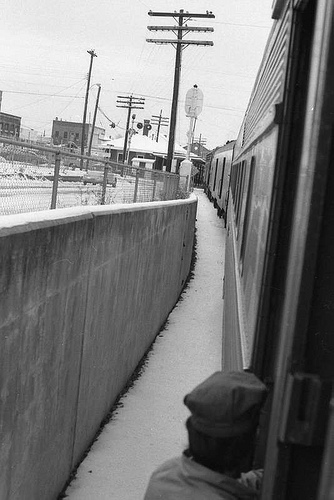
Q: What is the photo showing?
A: It is showing a train station.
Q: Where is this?
A: This is at the train station.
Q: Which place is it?
A: It is a train station.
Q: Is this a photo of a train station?
A: Yes, it is showing a train station.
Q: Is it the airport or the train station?
A: It is the train station.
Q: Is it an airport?
A: No, it is a train station.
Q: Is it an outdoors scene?
A: Yes, it is outdoors.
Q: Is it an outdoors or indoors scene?
A: It is outdoors.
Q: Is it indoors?
A: No, it is outdoors.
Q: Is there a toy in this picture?
A: No, there are no toys.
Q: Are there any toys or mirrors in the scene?
A: No, there are no toys or mirrors.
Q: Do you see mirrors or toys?
A: No, there are no toys or mirrors.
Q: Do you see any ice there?
A: Yes, there is ice.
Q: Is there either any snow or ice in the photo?
A: Yes, there is ice.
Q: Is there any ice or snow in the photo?
A: Yes, there is ice.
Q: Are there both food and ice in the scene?
A: No, there is ice but no food.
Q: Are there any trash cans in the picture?
A: No, there are no trash cans.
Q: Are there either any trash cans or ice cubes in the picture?
A: No, there are no trash cans or ice cubes.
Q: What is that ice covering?
A: The ice is covering the ground.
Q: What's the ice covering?
A: The ice is covering the ground.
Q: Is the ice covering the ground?
A: Yes, the ice is covering the ground.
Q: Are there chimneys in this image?
A: No, there are no chimneys.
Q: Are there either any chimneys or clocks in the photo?
A: No, there are no chimneys or clocks.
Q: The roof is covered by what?
A: The roof is covered by the snow.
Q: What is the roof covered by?
A: The roof is covered by the snow.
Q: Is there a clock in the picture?
A: No, there are no clocks.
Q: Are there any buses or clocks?
A: No, there are no clocks or buses.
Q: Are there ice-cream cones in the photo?
A: No, there are no ice-cream cones.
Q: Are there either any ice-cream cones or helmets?
A: No, there are no ice-cream cones or helmets.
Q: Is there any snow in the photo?
A: Yes, there is snow.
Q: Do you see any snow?
A: Yes, there is snow.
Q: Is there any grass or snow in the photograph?
A: Yes, there is snow.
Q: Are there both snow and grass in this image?
A: No, there is snow but no grass.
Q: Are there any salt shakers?
A: No, there are no salt shakers.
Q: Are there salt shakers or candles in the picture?
A: No, there are no salt shakers or candles.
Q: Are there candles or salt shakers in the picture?
A: No, there are no salt shakers or candles.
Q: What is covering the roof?
A: The snow is covering the roof.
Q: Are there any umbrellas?
A: No, there are no umbrellas.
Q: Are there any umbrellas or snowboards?
A: No, there are no umbrellas or snowboards.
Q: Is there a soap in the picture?
A: No, there are no soaps.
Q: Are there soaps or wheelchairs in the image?
A: No, there are no soaps or wheelchairs.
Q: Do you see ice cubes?
A: No, there are no ice cubes.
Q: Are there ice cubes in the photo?
A: No, there are no ice cubes.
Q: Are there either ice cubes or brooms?
A: No, there are no ice cubes or brooms.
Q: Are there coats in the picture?
A: Yes, there is a coat.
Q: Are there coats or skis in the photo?
A: Yes, there is a coat.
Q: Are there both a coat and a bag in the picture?
A: No, there is a coat but no bags.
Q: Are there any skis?
A: No, there are no skis.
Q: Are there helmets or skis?
A: No, there are no skis or helmets.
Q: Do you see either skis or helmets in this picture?
A: No, there are no skis or helmets.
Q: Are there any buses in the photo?
A: No, there are no buses.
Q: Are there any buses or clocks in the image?
A: No, there are no buses or clocks.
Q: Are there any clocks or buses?
A: No, there are no buses or clocks.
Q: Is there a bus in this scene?
A: No, there are no buses.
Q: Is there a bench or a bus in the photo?
A: No, there are no buses or benches.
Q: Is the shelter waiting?
A: Yes, the shelter is waiting.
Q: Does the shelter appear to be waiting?
A: Yes, the shelter is waiting.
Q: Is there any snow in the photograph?
A: Yes, there is snow.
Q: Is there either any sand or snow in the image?
A: Yes, there is snow.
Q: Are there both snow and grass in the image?
A: No, there is snow but no grass.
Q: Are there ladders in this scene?
A: No, there are no ladders.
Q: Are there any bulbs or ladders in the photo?
A: No, there are no ladders or bulbs.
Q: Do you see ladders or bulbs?
A: No, there are no ladders or bulbs.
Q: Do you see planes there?
A: No, there are no planes.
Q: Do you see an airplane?
A: No, there are no airplanes.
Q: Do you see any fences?
A: Yes, there is a fence.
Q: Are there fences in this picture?
A: Yes, there is a fence.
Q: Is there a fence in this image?
A: Yes, there is a fence.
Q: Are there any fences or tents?
A: Yes, there is a fence.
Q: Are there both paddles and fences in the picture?
A: No, there is a fence but no paddles.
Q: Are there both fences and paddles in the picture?
A: No, there is a fence but no paddles.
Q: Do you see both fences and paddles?
A: No, there is a fence but no paddles.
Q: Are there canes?
A: No, there are no canes.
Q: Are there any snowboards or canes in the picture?
A: No, there are no canes or snowboards.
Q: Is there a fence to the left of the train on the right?
A: Yes, there is a fence to the left of the train.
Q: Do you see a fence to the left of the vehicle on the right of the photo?
A: Yes, there is a fence to the left of the train.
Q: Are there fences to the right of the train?
A: No, the fence is to the left of the train.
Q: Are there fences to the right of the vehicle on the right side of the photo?
A: No, the fence is to the left of the train.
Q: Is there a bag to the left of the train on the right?
A: No, there is a fence to the left of the train.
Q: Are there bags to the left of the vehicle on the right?
A: No, there is a fence to the left of the train.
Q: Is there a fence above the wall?
A: Yes, there is a fence above the wall.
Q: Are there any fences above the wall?
A: Yes, there is a fence above the wall.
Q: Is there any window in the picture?
A: Yes, there is a window.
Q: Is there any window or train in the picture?
A: Yes, there is a window.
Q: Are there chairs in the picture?
A: No, there are no chairs.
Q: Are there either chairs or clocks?
A: No, there are no chairs or clocks.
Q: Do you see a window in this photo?
A: Yes, there is a window.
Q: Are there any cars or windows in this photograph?
A: Yes, there is a window.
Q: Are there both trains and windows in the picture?
A: Yes, there are both a window and a train.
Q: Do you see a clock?
A: No, there are no clocks.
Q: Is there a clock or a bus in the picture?
A: No, there are no clocks or buses.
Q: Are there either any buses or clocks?
A: No, there are no clocks or buses.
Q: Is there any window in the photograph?
A: Yes, there is a window.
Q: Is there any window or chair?
A: Yes, there is a window.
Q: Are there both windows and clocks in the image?
A: No, there is a window but no clocks.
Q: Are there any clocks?
A: No, there are no clocks.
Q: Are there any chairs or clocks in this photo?
A: No, there are no clocks or chairs.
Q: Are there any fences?
A: Yes, there is a fence.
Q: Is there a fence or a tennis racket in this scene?
A: Yes, there is a fence.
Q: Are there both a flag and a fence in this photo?
A: No, there is a fence but no flags.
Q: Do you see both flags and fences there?
A: No, there is a fence but no flags.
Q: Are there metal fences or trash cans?
A: Yes, there is a metal fence.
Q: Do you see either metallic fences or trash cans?
A: Yes, there is a metal fence.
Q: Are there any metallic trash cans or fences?
A: Yes, there is a metal fence.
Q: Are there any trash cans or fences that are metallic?
A: Yes, the fence is metallic.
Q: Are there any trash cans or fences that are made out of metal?
A: Yes, the fence is made of metal.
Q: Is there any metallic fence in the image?
A: Yes, there is a metal fence.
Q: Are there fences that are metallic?
A: Yes, there is a fence that is metallic.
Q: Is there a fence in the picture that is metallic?
A: Yes, there is a fence that is metallic.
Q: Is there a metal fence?
A: Yes, there is a fence that is made of metal.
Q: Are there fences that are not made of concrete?
A: Yes, there is a fence that is made of metal.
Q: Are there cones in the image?
A: No, there are no cones.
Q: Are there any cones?
A: No, there are no cones.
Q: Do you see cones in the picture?
A: No, there are no cones.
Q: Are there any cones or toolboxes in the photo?
A: No, there are no cones or toolboxes.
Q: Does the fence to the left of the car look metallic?
A: Yes, the fence is metallic.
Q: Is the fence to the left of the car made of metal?
A: Yes, the fence is made of metal.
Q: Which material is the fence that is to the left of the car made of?
A: The fence is made of metal.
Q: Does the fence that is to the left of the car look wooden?
A: No, the fence is metallic.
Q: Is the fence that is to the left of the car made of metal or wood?
A: The fence is made of metal.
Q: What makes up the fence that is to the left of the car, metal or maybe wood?
A: The fence is made of metal.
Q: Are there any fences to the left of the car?
A: Yes, there is a fence to the left of the car.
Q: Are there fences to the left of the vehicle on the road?
A: Yes, there is a fence to the left of the car.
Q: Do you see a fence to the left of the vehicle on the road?
A: Yes, there is a fence to the left of the car.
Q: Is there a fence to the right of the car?
A: No, the fence is to the left of the car.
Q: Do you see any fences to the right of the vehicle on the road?
A: No, the fence is to the left of the car.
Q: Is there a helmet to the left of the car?
A: No, there is a fence to the left of the car.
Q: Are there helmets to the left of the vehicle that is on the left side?
A: No, there is a fence to the left of the car.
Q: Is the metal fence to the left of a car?
A: Yes, the fence is to the left of a car.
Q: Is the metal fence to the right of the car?
A: No, the fence is to the left of the car.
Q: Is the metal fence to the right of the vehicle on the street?
A: No, the fence is to the left of the car.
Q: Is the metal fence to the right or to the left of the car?
A: The fence is to the left of the car.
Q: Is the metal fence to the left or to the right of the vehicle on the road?
A: The fence is to the left of the car.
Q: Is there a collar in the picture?
A: Yes, there is a collar.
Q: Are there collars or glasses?
A: Yes, there is a collar.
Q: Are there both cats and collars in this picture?
A: No, there is a collar but no cats.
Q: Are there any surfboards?
A: No, there are no surfboards.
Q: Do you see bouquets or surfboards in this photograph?
A: No, there are no surfboards or bouquets.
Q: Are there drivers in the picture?
A: No, there are no drivers.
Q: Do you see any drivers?
A: No, there are no drivers.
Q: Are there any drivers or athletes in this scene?
A: No, there are no drivers or athletes.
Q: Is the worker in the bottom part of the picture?
A: Yes, the worker is in the bottom of the image.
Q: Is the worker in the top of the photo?
A: No, the worker is in the bottom of the image.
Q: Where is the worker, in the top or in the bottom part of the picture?
A: The worker is in the bottom of the image.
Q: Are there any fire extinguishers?
A: No, there are no fire extinguishers.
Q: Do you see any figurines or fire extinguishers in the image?
A: No, there are no fire extinguishers or figurines.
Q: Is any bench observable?
A: No, there are no benches.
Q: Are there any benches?
A: No, there are no benches.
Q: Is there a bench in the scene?
A: No, there are no benches.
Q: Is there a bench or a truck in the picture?
A: No, there are no benches or trucks.